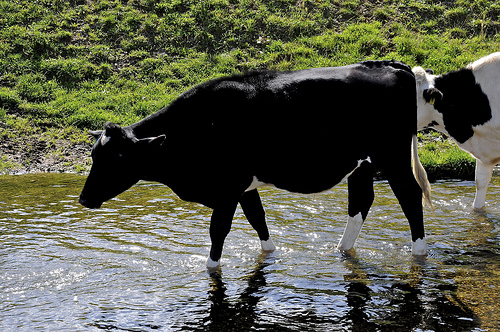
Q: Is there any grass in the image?
A: Yes, there is grass.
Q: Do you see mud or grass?
A: Yes, there is grass.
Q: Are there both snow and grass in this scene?
A: No, there is grass but no snow.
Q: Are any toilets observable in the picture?
A: No, there are no toilets.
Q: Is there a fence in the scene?
A: No, there are no fences.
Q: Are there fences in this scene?
A: No, there are no fences.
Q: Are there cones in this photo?
A: No, there are no cones.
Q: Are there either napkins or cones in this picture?
A: No, there are no cones or napkins.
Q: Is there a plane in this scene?
A: No, there are no airplanes.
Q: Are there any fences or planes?
A: No, there are no planes or fences.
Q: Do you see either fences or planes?
A: No, there are no planes or fences.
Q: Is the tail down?
A: Yes, the tail is down.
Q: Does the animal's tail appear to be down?
A: Yes, the tail is down.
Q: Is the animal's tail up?
A: No, the tail is down.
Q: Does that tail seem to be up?
A: No, the tail is down.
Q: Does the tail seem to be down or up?
A: The tail is down.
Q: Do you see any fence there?
A: No, there are no fences.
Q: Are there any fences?
A: No, there are no fences.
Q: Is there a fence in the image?
A: No, there are no fences.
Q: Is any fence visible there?
A: No, there are no fences.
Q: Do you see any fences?
A: No, there are no fences.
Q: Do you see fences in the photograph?
A: No, there are no fences.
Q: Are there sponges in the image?
A: No, there are no sponges.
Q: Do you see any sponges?
A: No, there are no sponges.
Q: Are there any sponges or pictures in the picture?
A: No, there are no sponges or pictures.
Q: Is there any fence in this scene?
A: No, there are no fences.